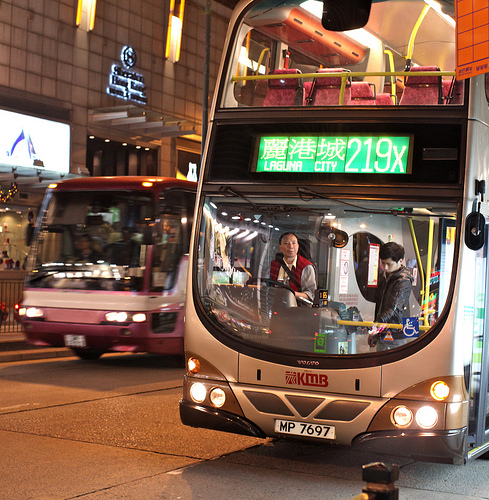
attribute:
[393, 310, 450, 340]
sticker — handicapped, accessible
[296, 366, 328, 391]
letters — red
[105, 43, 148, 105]
black sign — lighted, above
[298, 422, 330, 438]
7697 — written, numbers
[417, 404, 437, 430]
headlight — on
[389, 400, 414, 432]
headlight — on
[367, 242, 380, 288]
paper — red, white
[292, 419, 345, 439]
number — written, 7697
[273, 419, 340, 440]
license plate — white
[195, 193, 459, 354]
window — bus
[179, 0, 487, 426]
bus — black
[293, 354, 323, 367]
letters — silver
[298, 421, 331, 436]
numbers 7697 — written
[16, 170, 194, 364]
bus — pink, white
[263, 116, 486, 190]
sign — electronic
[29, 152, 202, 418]
bus — passenger